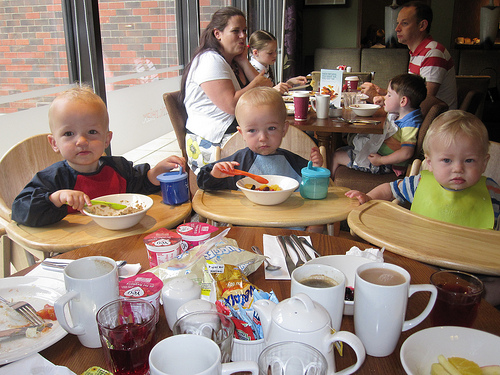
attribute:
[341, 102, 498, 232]
toddler — little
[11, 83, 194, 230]
toddler — little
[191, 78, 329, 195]
toddler — little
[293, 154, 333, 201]
sippee cup — light blue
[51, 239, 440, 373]
cups — multiple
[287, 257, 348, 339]
cup — tall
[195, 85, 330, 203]
boy — little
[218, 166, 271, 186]
spoon — orange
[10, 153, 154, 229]
boy — little, blue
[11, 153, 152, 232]
top — red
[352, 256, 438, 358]
cup — white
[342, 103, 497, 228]
boy — little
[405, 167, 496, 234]
bib — yellow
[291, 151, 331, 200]
sippy cup — blue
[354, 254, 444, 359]
mug — tall, white, coffee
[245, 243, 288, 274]
spoon — silver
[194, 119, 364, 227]
high chair — wooden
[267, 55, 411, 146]
table — brown, wooden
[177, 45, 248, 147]
sweater — woman's, white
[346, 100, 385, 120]
bowl — white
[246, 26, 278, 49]
hair — girl's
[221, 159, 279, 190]
spoon — orange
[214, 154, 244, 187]
hand — baby's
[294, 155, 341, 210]
cup — small, blue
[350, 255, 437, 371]
cup — large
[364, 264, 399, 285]
coffee — white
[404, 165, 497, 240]
bib — green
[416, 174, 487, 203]
neck — baby's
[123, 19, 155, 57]
bricks — red, black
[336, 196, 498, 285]
table — brown, wooden, baby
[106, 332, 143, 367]
liquid — red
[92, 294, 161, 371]
glass — clear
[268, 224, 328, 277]
silverware — set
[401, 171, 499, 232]
bib — green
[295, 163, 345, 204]
cup — blue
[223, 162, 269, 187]
spoon — orange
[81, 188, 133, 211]
spoon — green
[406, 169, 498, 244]
bib — green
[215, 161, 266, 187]
spoon — orange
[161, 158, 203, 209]
cup — sippy, blue